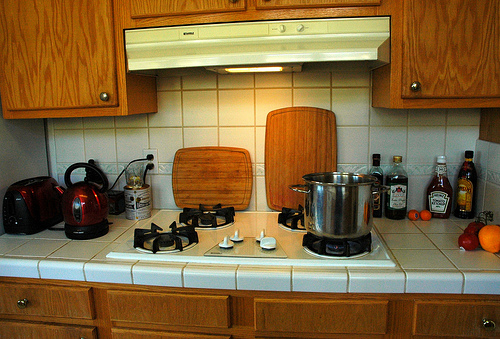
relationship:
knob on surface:
[217, 233, 235, 248] [122, 194, 422, 296]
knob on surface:
[231, 224, 244, 242] [122, 194, 422, 296]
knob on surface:
[255, 229, 267, 242] [122, 194, 422, 296]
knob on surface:
[256, 234, 276, 252] [122, 194, 422, 296]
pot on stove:
[282, 171, 382, 249] [154, 201, 383, 266]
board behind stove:
[263, 106, 337, 211] [132, 220, 197, 254]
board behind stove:
[172, 146, 253, 211] [132, 220, 197, 254]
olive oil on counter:
[383, 155, 408, 217] [3, 206, 496, 298]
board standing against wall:
[174, 147, 259, 207] [57, 98, 470, 225]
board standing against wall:
[265, 101, 340, 161] [57, 98, 470, 225]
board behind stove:
[172, 146, 253, 211] [115, 196, 398, 273]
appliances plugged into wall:
[12, 158, 119, 243] [58, 118, 171, 197]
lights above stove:
[214, 62, 303, 90] [158, 192, 392, 275]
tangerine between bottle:
[406, 207, 422, 222] [423, 151, 456, 221]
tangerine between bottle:
[418, 203, 431, 220] [423, 151, 456, 221]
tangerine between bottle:
[406, 207, 422, 222] [381, 150, 411, 225]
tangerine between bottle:
[418, 203, 431, 220] [381, 150, 411, 225]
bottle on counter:
[426, 155, 454, 219] [3, 206, 496, 298]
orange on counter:
[479, 224, 499, 253] [8, 218, 497, 299]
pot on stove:
[289, 172, 381, 239] [113, 205, 385, 272]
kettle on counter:
[52, 157, 112, 242] [3, 206, 496, 298]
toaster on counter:
[3, 176, 66, 236] [3, 206, 496, 298]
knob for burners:
[216, 229, 281, 252] [143, 184, 398, 269]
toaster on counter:
[10, 159, 75, 238] [3, 206, 496, 298]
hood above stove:
[119, 12, 394, 80] [100, 202, 400, 272]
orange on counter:
[477, 218, 498, 262] [394, 220, 471, 280]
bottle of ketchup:
[416, 154, 463, 222] [418, 151, 476, 215]